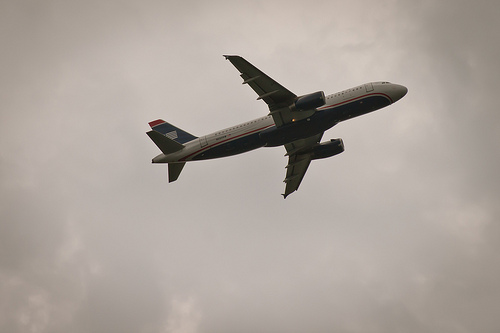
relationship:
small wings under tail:
[145, 129, 185, 182] [144, 119, 200, 184]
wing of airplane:
[281, 132, 323, 199] [144, 55, 408, 199]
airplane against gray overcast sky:
[144, 55, 408, 199] [113, 32, 158, 56]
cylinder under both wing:
[254, 123, 284, 138] [224, 53, 309, 118]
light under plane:
[282, 106, 302, 219] [172, 81, 382, 211]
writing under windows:
[216, 132, 231, 144] [213, 112, 271, 136]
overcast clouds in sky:
[53, 49, 278, 143] [18, 202, 181, 317]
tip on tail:
[145, 115, 165, 128] [149, 114, 195, 139]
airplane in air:
[144, 55, 408, 199] [37, 64, 497, 214]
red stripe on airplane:
[205, 119, 276, 154] [144, 55, 408, 199]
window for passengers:
[233, 123, 239, 129] [189, 105, 264, 169]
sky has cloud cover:
[0, 0, 499, 331] [308, 204, 498, 314]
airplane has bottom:
[144, 55, 408, 199] [192, 89, 405, 166]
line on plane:
[195, 84, 383, 152] [138, 47, 395, 209]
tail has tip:
[147, 117, 195, 192] [143, 110, 172, 130]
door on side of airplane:
[365, 82, 374, 92] [144, 55, 408, 199]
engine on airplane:
[296, 91, 326, 111] [144, 55, 408, 199]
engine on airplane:
[313, 138, 344, 159] [144, 55, 408, 199]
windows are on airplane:
[213, 110, 274, 137] [144, 55, 408, 199]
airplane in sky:
[144, 55, 408, 199] [1, 0, 497, 90]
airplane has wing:
[144, 55, 408, 199] [222, 53, 297, 115]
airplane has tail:
[142, 52, 409, 202] [142, 117, 199, 182]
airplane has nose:
[144, 55, 408, 199] [388, 78, 413, 103]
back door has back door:
[198, 135, 208, 148] [190, 138, 213, 153]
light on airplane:
[291, 118, 296, 122] [144, 55, 408, 199]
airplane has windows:
[144, 55, 408, 199] [207, 112, 276, 144]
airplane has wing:
[144, 55, 408, 199] [220, 46, 306, 129]